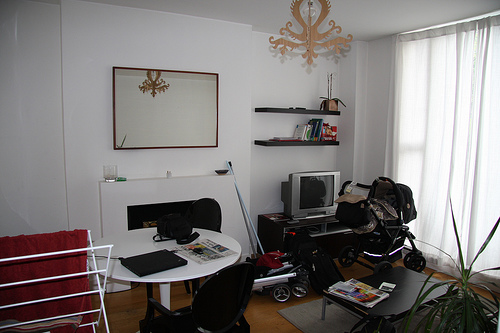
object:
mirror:
[111, 66, 219, 151]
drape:
[381, 14, 499, 290]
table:
[86, 227, 241, 320]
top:
[88, 227, 243, 284]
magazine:
[327, 274, 389, 309]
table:
[319, 265, 499, 332]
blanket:
[0, 229, 92, 329]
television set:
[279, 170, 341, 225]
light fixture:
[267, 0, 356, 67]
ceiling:
[87, 0, 497, 41]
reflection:
[137, 70, 173, 98]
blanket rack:
[0, 243, 115, 332]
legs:
[318, 300, 325, 324]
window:
[394, 11, 499, 291]